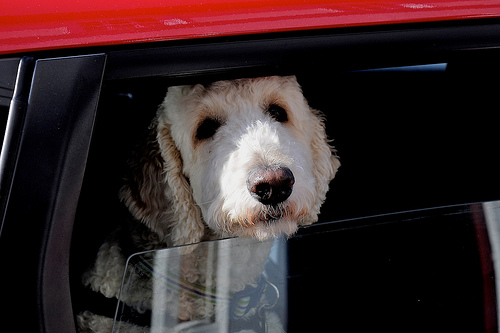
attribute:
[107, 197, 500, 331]
window — clear, open, part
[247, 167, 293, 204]
nose — black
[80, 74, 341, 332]
dog — looking, white, sitting, shaggy, staring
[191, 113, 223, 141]
eye — dark, black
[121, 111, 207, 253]
ear — large, edge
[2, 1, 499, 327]
car — black, part, red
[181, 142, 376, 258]
snout — white